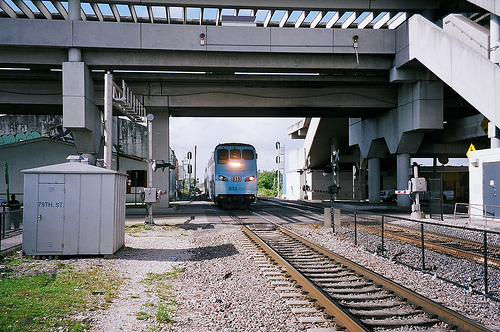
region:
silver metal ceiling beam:
[373, 10, 396, 35]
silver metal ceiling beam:
[358, 9, 378, 28]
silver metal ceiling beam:
[341, 12, 361, 27]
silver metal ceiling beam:
[308, 8, 327, 28]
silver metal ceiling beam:
[293, 6, 308, 30]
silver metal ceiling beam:
[277, 8, 295, 28]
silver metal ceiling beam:
[262, 7, 276, 26]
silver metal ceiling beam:
[91, 0, 102, 19]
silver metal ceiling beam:
[110, 0, 121, 23]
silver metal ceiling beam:
[128, 1, 139, 24]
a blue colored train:
[204, 139, 261, 204]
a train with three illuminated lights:
[204, 141, 259, 206]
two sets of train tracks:
[222, 195, 497, 328]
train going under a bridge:
[0, 0, 499, 258]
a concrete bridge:
[3, 3, 499, 253]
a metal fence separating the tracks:
[311, 208, 498, 301]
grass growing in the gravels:
[0, 268, 199, 328]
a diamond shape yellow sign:
[463, 143, 478, 158]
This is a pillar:
[393, 148, 427, 226]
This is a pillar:
[366, 141, 387, 212]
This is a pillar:
[355, 151, 372, 212]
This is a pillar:
[102, 63, 124, 190]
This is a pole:
[416, 209, 439, 284]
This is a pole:
[481, 224, 497, 311]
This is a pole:
[376, 211, 388, 263]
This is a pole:
[329, 201, 345, 237]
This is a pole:
[139, 109, 166, 224]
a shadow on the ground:
[173, 241, 236, 261]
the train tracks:
[298, 265, 370, 289]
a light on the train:
[227, 156, 242, 170]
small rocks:
[232, 285, 261, 326]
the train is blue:
[215, 144, 260, 198]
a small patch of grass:
[7, 266, 69, 326]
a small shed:
[23, 172, 108, 248]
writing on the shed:
[30, 190, 65, 211]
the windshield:
[217, 147, 249, 157]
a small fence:
[407, 221, 487, 279]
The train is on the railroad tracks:
[10, 22, 480, 315]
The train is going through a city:
[25, 26, 470, 323]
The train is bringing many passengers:
[17, 42, 463, 328]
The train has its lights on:
[36, 53, 448, 313]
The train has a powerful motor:
[36, 40, 482, 308]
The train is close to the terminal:
[25, 45, 470, 311]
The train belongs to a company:
[15, 30, 468, 316]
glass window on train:
[217, 147, 229, 161]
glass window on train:
[228, 147, 240, 158]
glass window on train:
[210, 158, 216, 166]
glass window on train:
[205, 162, 212, 167]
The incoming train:
[195, 133, 275, 205]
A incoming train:
[213, 127, 279, 219]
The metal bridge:
[1, 13, 406, 104]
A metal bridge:
[1, 14, 406, 103]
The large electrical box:
[14, 153, 145, 265]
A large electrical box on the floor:
[11, 155, 136, 265]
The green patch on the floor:
[2, 245, 137, 325]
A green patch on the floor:
[4, 257, 137, 329]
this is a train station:
[36, 24, 453, 325]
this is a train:
[204, 135, 312, 215]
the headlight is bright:
[189, 146, 288, 213]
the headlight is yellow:
[195, 139, 255, 199]